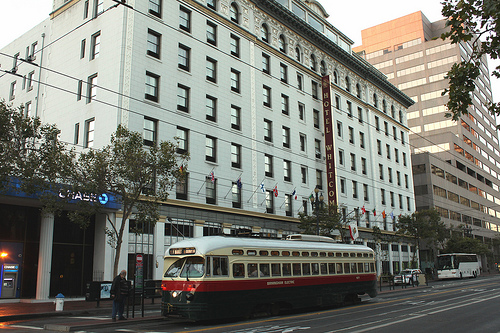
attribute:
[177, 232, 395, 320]
trolley — red, white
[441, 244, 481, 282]
bus — white, parked, in city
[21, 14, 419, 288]
building — hotel, bank, white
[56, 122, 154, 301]
tree — scrawny, small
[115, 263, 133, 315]
man — standing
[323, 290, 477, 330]
lines — white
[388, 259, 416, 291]
car — white, in background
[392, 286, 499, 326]
road — paved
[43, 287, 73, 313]
hydrant — white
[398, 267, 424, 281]
van — parked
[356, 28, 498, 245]
building — brown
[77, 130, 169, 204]
leaves — green